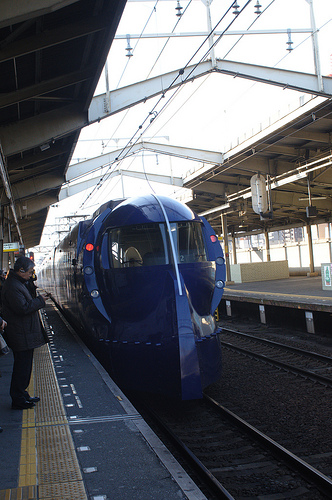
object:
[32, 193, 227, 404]
train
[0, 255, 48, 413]
man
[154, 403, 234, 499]
tracks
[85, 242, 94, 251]
light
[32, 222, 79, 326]
system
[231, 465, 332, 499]
front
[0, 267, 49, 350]
jacket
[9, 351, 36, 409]
legs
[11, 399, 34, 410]
feet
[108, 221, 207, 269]
window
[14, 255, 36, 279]
head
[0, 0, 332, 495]
station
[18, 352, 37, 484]
line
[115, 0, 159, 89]
wires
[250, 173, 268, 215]
sign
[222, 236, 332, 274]
wall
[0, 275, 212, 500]
platform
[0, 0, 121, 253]
roof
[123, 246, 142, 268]
seat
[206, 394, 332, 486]
track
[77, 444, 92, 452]
spot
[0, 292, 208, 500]
sidewalk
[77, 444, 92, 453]
square